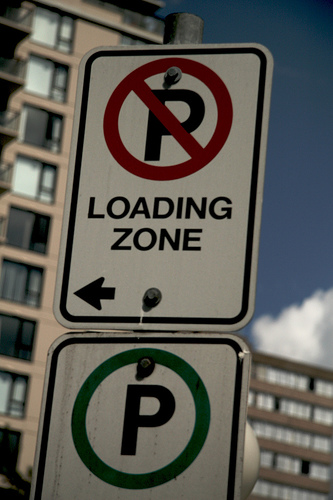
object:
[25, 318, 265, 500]
sign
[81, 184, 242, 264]
letters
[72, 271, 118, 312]
arrow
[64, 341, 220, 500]
parking symbol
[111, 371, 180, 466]
p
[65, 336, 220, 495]
circle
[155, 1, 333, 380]
sky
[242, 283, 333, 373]
cloud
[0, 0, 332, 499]
building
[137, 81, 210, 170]
p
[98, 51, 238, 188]
circle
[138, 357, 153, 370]
bolt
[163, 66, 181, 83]
bolt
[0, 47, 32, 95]
balconies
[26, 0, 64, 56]
curtain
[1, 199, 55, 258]
window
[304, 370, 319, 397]
windows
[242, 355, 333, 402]
top floor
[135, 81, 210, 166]
slash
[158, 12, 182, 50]
pole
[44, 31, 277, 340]
signs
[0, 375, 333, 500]
street